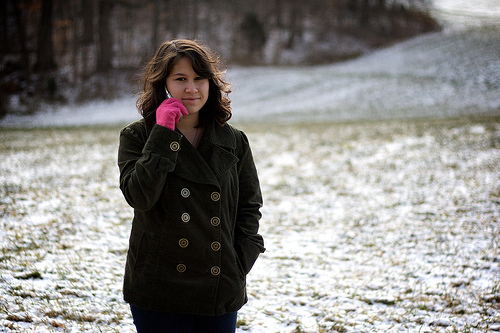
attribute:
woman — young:
[118, 39, 267, 333]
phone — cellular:
[163, 85, 183, 123]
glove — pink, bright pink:
[156, 98, 188, 131]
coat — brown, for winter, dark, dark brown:
[118, 109, 267, 316]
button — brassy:
[181, 188, 190, 198]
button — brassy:
[181, 212, 191, 223]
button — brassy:
[178, 238, 189, 248]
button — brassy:
[177, 263, 187, 273]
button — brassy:
[210, 191, 221, 201]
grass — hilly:
[0, 0, 499, 333]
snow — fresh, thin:
[1, 0, 500, 332]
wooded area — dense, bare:
[0, 0, 443, 121]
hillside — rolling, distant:
[0, 0, 499, 127]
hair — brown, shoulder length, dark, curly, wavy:
[130, 37, 237, 129]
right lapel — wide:
[144, 108, 221, 187]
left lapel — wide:
[196, 117, 240, 178]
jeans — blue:
[130, 303, 238, 332]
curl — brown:
[136, 90, 155, 115]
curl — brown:
[218, 104, 232, 125]